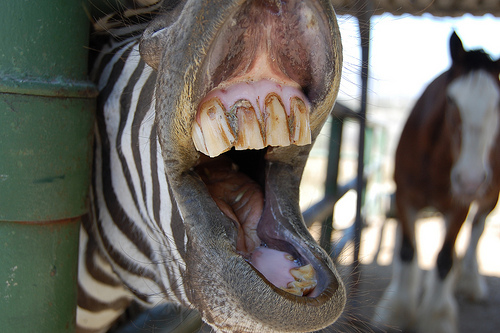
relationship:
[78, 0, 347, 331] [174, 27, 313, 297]
zebra with mouth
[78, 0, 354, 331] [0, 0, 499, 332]
zebra in stable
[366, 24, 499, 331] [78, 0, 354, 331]
horse next to zebra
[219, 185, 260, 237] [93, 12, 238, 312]
tongue of zebra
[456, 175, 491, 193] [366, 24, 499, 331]
nose of horse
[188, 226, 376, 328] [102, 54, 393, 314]
lip of zebra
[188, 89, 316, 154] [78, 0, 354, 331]
teeth of zebra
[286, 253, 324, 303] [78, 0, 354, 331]
bottom teeth of zebra